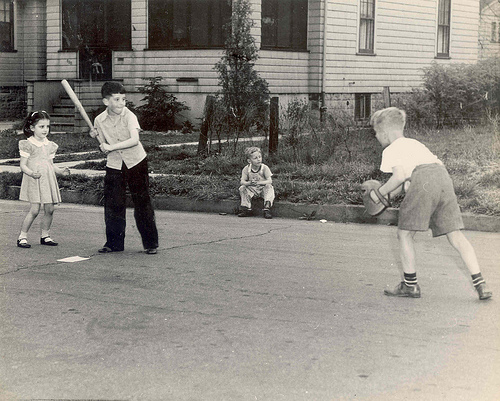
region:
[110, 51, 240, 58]
white siding on porch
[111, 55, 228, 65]
white siding on porch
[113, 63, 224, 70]
white siding on porch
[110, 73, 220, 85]
white siding on porch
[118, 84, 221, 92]
white siding on porch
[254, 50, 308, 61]
white siding on porch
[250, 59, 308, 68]
white siding on porch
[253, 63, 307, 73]
white siding on porch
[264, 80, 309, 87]
white siding on porch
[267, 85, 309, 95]
white siding on porch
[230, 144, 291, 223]
the boy is sitting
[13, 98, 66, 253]
girl is wearing a dress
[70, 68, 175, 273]
this is a boy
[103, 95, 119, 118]
the boy is light skinned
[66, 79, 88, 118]
this is a bat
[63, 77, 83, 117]
the bat is white in color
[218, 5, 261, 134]
this is a tree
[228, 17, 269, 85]
the leaves are green in color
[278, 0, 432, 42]
this is a building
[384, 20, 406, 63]
this is the wall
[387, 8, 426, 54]
the wall is white in color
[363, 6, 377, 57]
this is a window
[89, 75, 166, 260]
A boy getting ready to hit a ball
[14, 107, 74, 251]
A girl standing behind the boy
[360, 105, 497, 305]
A boy preparing to pitch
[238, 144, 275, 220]
A boy sitting on the curb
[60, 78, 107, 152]
A small wood bat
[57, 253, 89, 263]
A piece of paper on the ground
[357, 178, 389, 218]
The boy's leather mitt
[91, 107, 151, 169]
A button down shirt on the boy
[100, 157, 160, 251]
The boy's black pants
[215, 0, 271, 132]
A small tree in the yard